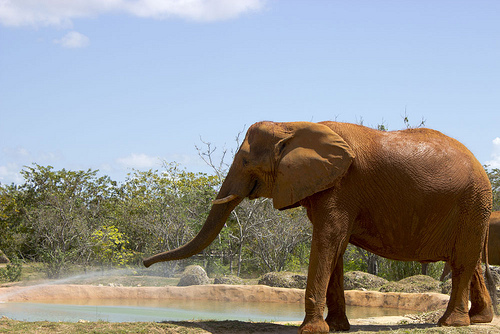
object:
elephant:
[439, 210, 499, 283]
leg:
[328, 253, 346, 315]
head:
[141, 120, 289, 268]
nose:
[142, 258, 152, 268]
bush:
[157, 160, 316, 270]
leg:
[446, 257, 476, 313]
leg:
[303, 213, 346, 323]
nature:
[0, 10, 500, 334]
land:
[0, 261, 499, 334]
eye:
[243, 159, 250, 164]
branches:
[0, 162, 125, 286]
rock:
[175, 262, 212, 287]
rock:
[211, 272, 246, 286]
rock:
[258, 269, 307, 289]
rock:
[345, 269, 386, 290]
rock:
[381, 273, 443, 295]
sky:
[0, 0, 497, 198]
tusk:
[212, 194, 239, 205]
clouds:
[0, 0, 500, 185]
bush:
[90, 221, 142, 268]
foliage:
[115, 239, 118, 244]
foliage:
[107, 234, 112, 239]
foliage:
[107, 225, 115, 229]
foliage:
[119, 258, 126, 265]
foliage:
[91, 229, 103, 237]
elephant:
[142, 120, 493, 334]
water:
[5, 295, 432, 322]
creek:
[1, 301, 437, 325]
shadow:
[163, 319, 436, 333]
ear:
[273, 123, 356, 209]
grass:
[2, 312, 500, 333]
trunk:
[142, 167, 248, 269]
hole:
[0, 289, 433, 329]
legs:
[471, 254, 492, 311]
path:
[0, 285, 500, 334]